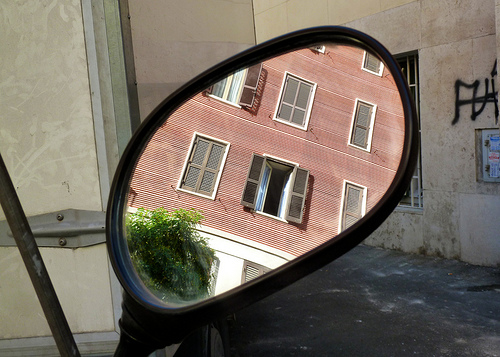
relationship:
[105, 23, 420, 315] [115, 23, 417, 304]
frame on mirror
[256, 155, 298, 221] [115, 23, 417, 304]
window in mirror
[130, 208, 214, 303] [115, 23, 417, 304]
tree in mirror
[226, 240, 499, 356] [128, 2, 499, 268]
ground by structure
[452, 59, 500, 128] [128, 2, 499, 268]
graffiti on structure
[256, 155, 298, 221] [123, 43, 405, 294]
window on building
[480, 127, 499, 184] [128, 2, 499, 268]
sign on structure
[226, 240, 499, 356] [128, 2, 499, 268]
ground on structure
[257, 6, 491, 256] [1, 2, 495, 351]
wall on building